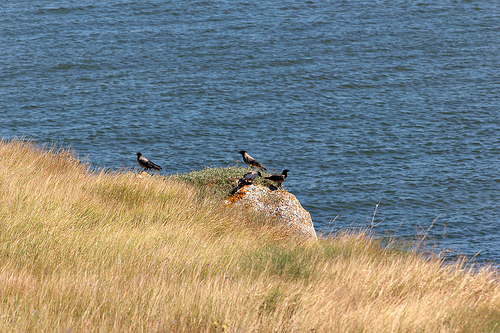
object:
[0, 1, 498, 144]
water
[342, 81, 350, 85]
ripples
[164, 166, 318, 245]
rock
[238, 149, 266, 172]
bird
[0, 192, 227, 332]
grass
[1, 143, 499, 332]
field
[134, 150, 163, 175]
lichen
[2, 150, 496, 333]
meadow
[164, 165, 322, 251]
cliff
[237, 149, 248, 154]
head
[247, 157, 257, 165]
wing